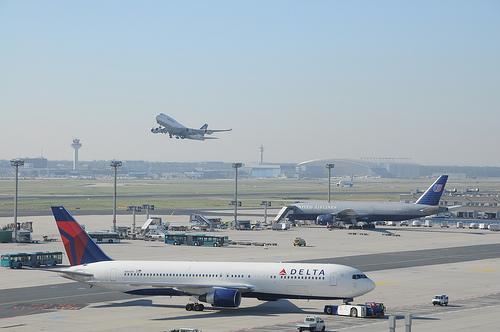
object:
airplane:
[41, 194, 385, 318]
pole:
[432, 301, 435, 304]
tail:
[415, 175, 449, 218]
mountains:
[431, 162, 497, 177]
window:
[352, 275, 356, 279]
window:
[357, 275, 361, 279]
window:
[361, 275, 364, 278]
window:
[363, 275, 366, 278]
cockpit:
[352, 268, 366, 298]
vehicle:
[296, 316, 325, 332]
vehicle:
[191, 234, 228, 247]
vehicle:
[164, 233, 187, 245]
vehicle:
[28, 251, 65, 267]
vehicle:
[1, 253, 32, 269]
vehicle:
[293, 237, 306, 246]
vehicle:
[432, 295, 448, 307]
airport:
[1, 206, 498, 330]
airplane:
[284, 174, 448, 229]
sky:
[0, 1, 499, 145]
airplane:
[150, 113, 231, 141]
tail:
[43, 206, 113, 291]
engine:
[199, 289, 242, 307]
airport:
[3, 171, 498, 329]